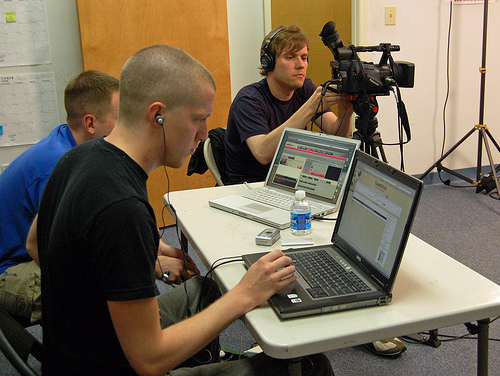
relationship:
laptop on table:
[240, 151, 423, 322] [163, 182, 499, 374]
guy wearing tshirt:
[24, 46, 333, 375] [36, 135, 161, 375]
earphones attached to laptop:
[154, 110, 245, 366] [240, 151, 423, 322]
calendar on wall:
[1, 69, 63, 151] [2, 2, 498, 189]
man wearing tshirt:
[2, 71, 120, 324] [1, 123, 75, 275]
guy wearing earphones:
[24, 46, 333, 375] [154, 110, 245, 366]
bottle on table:
[288, 189, 313, 246] [163, 182, 499, 374]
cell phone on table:
[254, 222, 282, 246] [163, 182, 499, 374]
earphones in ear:
[154, 110, 245, 366] [147, 100, 166, 130]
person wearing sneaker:
[224, 21, 407, 358] [360, 338, 409, 358]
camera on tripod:
[320, 20, 417, 146] [346, 96, 391, 164]